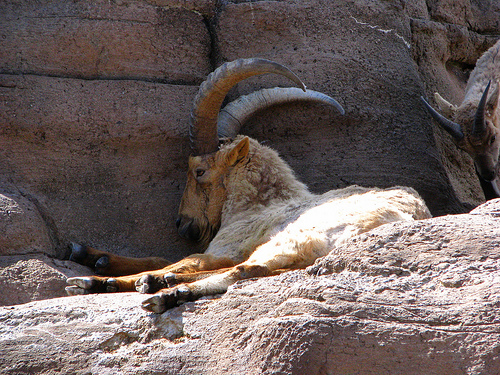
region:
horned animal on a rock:
[66, 57, 430, 314]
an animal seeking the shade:
[66, 58, 431, 313]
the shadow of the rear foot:
[152, 302, 189, 343]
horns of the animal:
[183, 59, 345, 154]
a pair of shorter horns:
[418, 79, 492, 139]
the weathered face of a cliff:
[0, 202, 497, 373]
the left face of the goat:
[177, 153, 223, 234]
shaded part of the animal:
[64, 1, 420, 272]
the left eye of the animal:
[191, 164, 205, 175]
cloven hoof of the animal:
[61, 275, 88, 297]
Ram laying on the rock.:
[60, 52, 445, 316]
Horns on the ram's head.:
[174, 47, 353, 157]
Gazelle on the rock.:
[420, 34, 499, 204]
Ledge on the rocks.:
[0, 198, 498, 373]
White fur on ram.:
[167, 113, 422, 270]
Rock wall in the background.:
[0, 2, 496, 262]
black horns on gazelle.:
[418, 80, 490, 145]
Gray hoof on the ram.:
[63, 236, 84, 261]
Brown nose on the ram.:
[172, 200, 199, 239]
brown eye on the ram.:
[190, 161, 210, 183]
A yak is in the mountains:
[140, 115, 497, 307]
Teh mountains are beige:
[201, 275, 463, 354]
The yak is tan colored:
[160, 143, 497, 347]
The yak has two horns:
[169, 55, 421, 219]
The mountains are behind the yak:
[34, 23, 195, 199]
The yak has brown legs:
[89, 243, 271, 307]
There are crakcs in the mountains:
[393, 60, 498, 173]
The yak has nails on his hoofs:
[52, 265, 124, 315]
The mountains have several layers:
[51, 14, 185, 201]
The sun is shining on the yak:
[240, 183, 382, 223]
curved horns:
[149, 30, 351, 139]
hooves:
[53, 272, 105, 298]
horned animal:
[167, 73, 441, 307]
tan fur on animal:
[236, 165, 320, 242]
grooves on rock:
[279, 269, 494, 365]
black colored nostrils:
[167, 215, 183, 233]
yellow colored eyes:
[194, 168, 212, 178]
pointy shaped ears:
[224, 135, 271, 177]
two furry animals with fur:
[104, 48, 499, 244]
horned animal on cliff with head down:
[416, 76, 498, 203]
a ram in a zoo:
[36, 40, 441, 328]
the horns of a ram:
[158, 40, 348, 151]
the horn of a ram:
[229, 90, 351, 135]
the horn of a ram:
[174, 53, 306, 145]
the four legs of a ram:
[41, 229, 266, 331]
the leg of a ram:
[142, 286, 277, 329]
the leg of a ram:
[133, 272, 230, 296]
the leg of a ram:
[59, 272, 175, 293]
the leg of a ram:
[65, 236, 167, 273]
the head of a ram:
[163, 135, 230, 245]